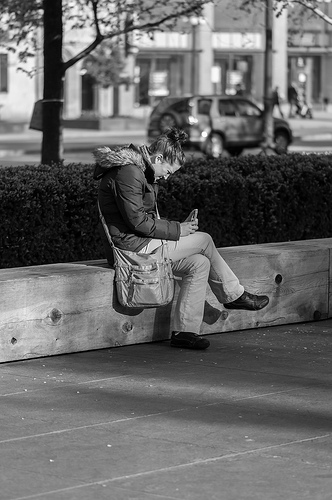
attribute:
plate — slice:
[178, 207, 204, 238]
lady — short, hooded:
[91, 126, 269, 350]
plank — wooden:
[0, 235, 330, 364]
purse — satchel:
[93, 195, 175, 308]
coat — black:
[93, 140, 182, 252]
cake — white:
[183, 209, 199, 224]